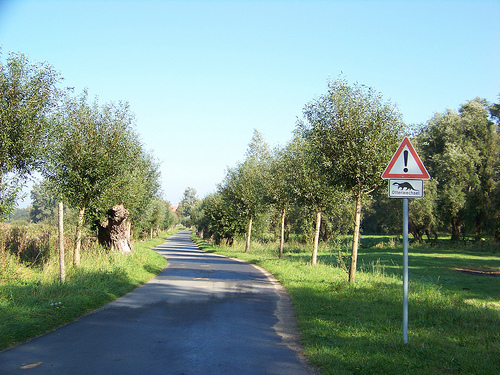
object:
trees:
[424, 96, 479, 252]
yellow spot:
[21, 360, 41, 367]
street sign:
[378, 135, 433, 180]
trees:
[273, 89, 353, 271]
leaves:
[341, 123, 346, 129]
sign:
[385, 177, 425, 199]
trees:
[292, 75, 404, 288]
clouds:
[441, 32, 499, 92]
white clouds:
[172, 140, 225, 182]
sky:
[0, 0, 500, 203]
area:
[7, 185, 499, 373]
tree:
[40, 86, 140, 272]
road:
[0, 207, 307, 375]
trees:
[141, 195, 164, 244]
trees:
[219, 127, 277, 253]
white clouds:
[147, 93, 225, 178]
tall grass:
[0, 253, 146, 341]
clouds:
[361, 10, 404, 81]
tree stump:
[93, 204, 132, 256]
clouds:
[4, 28, 119, 57]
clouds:
[277, 32, 324, 66]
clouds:
[112, 37, 212, 72]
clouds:
[256, 106, 293, 131]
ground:
[0, 211, 500, 374]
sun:
[42, 13, 322, 149]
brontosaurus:
[392, 181, 419, 193]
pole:
[399, 194, 411, 346]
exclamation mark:
[403, 148, 411, 174]